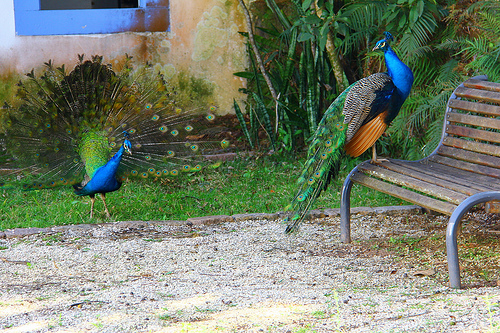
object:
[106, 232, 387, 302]
surface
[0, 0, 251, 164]
wall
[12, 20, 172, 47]
frame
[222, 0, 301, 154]
plants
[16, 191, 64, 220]
grass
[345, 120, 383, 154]
feathers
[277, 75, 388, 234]
wing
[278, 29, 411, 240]
peacock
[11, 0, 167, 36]
window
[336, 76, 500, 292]
bench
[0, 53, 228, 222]
peacock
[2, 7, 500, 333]
area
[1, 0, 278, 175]
building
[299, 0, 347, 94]
trees